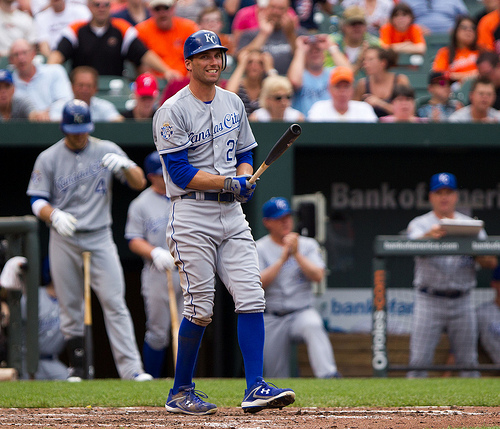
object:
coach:
[406, 170, 497, 378]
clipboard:
[441, 218, 481, 238]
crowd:
[0, 0, 499, 123]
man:
[27, 99, 156, 380]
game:
[0, 119, 500, 427]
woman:
[249, 75, 305, 123]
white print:
[204, 33, 216, 44]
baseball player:
[150, 27, 297, 414]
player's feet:
[237, 379, 297, 419]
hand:
[223, 174, 260, 200]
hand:
[234, 175, 257, 203]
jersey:
[152, 84, 260, 197]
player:
[124, 146, 191, 375]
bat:
[79, 250, 97, 378]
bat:
[164, 262, 184, 371]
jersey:
[27, 133, 132, 238]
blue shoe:
[162, 386, 218, 416]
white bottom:
[239, 390, 296, 410]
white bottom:
[164, 404, 217, 416]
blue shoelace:
[173, 387, 207, 402]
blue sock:
[237, 308, 266, 389]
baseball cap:
[184, 30, 229, 72]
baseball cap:
[429, 172, 457, 191]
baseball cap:
[62, 99, 96, 135]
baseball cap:
[144, 151, 164, 174]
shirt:
[381, 21, 426, 48]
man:
[381, 1, 428, 54]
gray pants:
[165, 192, 265, 326]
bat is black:
[265, 124, 302, 165]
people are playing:
[23, 27, 500, 415]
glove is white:
[50, 207, 76, 238]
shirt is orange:
[129, 11, 209, 80]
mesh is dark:
[382, 253, 500, 379]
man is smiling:
[194, 51, 223, 82]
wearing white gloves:
[51, 151, 128, 238]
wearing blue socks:
[140, 341, 166, 376]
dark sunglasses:
[90, 0, 110, 10]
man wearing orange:
[381, 19, 427, 51]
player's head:
[180, 28, 229, 84]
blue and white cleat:
[241, 376, 296, 414]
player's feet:
[160, 381, 220, 422]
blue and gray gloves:
[222, 174, 260, 203]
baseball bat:
[234, 124, 302, 198]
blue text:
[190, 110, 241, 145]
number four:
[94, 178, 108, 196]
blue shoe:
[234, 380, 299, 414]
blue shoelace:
[254, 376, 278, 390]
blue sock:
[172, 317, 207, 395]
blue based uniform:
[150, 85, 296, 384]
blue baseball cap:
[260, 196, 290, 218]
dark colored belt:
[181, 191, 236, 203]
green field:
[0, 376, 499, 407]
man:
[42, 0, 180, 86]